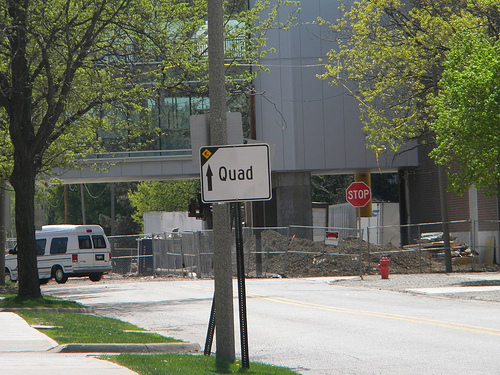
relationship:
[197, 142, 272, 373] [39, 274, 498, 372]
direction sign on street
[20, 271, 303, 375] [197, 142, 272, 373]
street side has direction sign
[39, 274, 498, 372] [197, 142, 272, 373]
street shows direction sign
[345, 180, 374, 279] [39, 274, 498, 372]
stop sign on street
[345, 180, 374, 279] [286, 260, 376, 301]
stop sign on corner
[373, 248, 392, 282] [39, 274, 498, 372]
hydrant on street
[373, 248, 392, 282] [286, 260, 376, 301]
hydrant near corner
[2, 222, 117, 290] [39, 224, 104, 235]
van has a hi top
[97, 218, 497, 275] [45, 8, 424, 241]
fence around building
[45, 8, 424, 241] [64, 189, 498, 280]
building in construction site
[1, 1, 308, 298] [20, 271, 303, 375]
tree on street side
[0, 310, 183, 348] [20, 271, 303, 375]
green grass on street side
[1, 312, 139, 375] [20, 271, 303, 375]
sidewalk on street side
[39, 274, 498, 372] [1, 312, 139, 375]
street has sidewalk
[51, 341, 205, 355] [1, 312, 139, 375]
curb from sidewalk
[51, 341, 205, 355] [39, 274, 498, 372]
curb to street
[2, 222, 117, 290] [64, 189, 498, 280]
van parked at construction site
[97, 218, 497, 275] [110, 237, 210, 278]
fence made of chain link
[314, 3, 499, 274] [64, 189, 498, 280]
tree at construction site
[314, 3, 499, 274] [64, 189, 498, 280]
tree next to construction site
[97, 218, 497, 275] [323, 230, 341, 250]
fence has danger sign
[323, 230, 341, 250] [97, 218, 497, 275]
danger sign attached to fence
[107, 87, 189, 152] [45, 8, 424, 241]
window on building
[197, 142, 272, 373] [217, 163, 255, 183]
direction sign says quad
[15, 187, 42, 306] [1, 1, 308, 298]
trunk of tree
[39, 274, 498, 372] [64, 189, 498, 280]
street has construction site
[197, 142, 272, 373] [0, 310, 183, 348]
direction sign on green grass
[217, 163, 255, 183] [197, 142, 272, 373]
quad on direction sign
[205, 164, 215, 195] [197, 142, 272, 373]
arrow on direction sign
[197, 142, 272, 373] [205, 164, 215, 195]
direction sign shows an arrow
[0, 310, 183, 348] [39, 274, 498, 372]
green grass growing near street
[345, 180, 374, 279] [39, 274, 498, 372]
stop sign across street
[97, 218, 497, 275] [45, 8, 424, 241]
fence across from of building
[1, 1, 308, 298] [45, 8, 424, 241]
tree in front of building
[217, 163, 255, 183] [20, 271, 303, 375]
quad on road side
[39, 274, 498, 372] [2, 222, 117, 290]
street has van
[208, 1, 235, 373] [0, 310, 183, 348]
pole in green grass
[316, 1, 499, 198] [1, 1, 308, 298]
green leaves on tree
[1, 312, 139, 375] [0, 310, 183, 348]
sidewalk next to green grass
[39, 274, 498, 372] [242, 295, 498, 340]
street has yellow lines